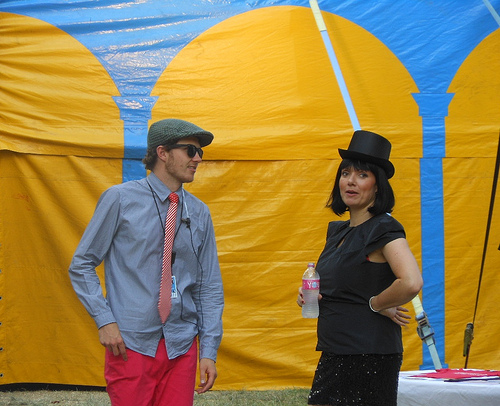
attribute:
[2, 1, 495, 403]
picture — outdoor, outdoors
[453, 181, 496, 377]
strap — black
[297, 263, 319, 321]
water bottle — clear 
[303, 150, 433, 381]
clothes — black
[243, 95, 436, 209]
hat — black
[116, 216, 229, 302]
tie — pink